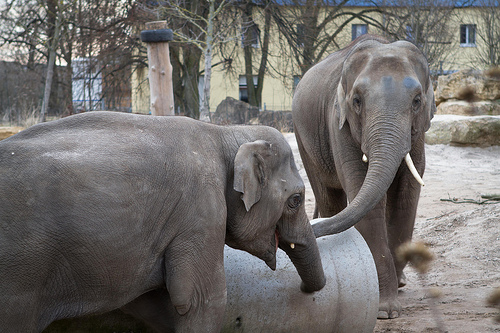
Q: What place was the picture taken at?
A: It was taken at the pen.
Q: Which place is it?
A: It is a pen.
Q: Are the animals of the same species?
A: Yes, all the animals are elephants.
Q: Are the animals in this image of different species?
A: No, all the animals are elephants.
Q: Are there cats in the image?
A: No, there are no cats.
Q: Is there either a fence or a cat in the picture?
A: No, there are no cats or fences.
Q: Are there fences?
A: No, there are no fences.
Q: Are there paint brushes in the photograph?
A: No, there are no paint brushes.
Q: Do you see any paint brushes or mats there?
A: No, there are no paint brushes or mats.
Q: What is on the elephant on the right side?
A: The trunk is on the elephant.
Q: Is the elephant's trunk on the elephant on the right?
A: Yes, the trunk is on the elephant.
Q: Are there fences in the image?
A: No, there are no fences.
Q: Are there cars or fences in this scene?
A: No, there are no fences or cars.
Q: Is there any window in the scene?
A: Yes, there is a window.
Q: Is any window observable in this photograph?
A: Yes, there is a window.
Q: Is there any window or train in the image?
A: Yes, there is a window.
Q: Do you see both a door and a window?
A: No, there is a window but no doors.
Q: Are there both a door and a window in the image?
A: No, there is a window but no doors.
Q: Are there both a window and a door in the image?
A: No, there is a window but no doors.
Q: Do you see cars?
A: No, there are no cars.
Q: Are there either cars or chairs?
A: No, there are no cars or chairs.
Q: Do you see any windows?
A: Yes, there is a window.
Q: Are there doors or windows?
A: Yes, there is a window.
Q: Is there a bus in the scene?
A: No, there are no buses.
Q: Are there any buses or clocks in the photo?
A: No, there are no buses or clocks.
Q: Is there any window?
A: Yes, there is a window.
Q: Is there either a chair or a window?
A: Yes, there is a window.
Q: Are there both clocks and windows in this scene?
A: No, there is a window but no clocks.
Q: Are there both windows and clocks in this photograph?
A: No, there is a window but no clocks.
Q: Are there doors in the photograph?
A: No, there are no doors.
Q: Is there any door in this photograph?
A: No, there are no doors.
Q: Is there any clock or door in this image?
A: No, there are no doors or clocks.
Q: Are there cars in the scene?
A: No, there are no cars.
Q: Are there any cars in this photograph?
A: No, there are no cars.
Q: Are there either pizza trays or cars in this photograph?
A: No, there are no cars or pizza trays.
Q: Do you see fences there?
A: No, there are no fences.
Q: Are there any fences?
A: No, there are no fences.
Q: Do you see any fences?
A: No, there are no fences.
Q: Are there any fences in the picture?
A: No, there are no fences.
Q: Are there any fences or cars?
A: No, there are no fences or cars.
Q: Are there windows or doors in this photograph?
A: Yes, there is a window.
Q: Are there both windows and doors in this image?
A: No, there is a window but no doors.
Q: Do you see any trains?
A: No, there are no trains.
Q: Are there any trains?
A: No, there are no trains.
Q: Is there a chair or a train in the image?
A: No, there are no trains or chairs.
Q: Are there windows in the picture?
A: Yes, there is a window.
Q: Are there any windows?
A: Yes, there is a window.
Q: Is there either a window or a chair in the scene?
A: Yes, there is a window.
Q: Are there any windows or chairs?
A: Yes, there is a window.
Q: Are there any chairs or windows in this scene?
A: Yes, there is a window.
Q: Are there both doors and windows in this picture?
A: No, there is a window but no doors.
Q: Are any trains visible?
A: No, there are no trains.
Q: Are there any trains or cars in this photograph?
A: No, there are no trains or cars.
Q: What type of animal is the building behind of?
A: The building is behind the elephant.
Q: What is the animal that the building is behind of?
A: The animal is an elephant.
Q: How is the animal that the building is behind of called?
A: The animal is an elephant.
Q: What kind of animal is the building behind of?
A: The building is behind the elephant.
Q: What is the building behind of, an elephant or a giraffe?
A: The building is behind an elephant.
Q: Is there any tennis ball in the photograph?
A: No, there are no tennis balls.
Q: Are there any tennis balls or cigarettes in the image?
A: No, there are no tennis balls or cigarettes.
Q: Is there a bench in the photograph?
A: No, there are no benches.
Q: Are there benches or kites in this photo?
A: No, there are no benches or kites.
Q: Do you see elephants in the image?
A: Yes, there is an elephant.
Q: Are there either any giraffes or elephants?
A: Yes, there is an elephant.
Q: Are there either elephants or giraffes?
A: Yes, there is an elephant.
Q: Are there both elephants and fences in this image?
A: No, there is an elephant but no fences.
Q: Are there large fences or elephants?
A: Yes, there is a large elephant.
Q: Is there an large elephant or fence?
A: Yes, there is a large elephant.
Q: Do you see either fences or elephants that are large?
A: Yes, the elephant is large.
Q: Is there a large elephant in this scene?
A: Yes, there is a large elephant.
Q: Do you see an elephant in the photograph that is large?
A: Yes, there is an elephant that is large.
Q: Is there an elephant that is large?
A: Yes, there is an elephant that is large.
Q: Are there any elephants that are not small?
A: Yes, there is a large elephant.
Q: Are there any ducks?
A: No, there are no ducks.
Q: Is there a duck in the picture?
A: No, there are no ducks.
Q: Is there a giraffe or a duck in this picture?
A: No, there are no ducks or giraffes.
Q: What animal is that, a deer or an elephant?
A: That is an elephant.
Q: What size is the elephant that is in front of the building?
A: The elephant is large.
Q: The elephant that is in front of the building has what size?
A: The elephant is large.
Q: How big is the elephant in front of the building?
A: The elephant is large.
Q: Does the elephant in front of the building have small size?
A: No, the elephant is large.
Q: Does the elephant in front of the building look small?
A: No, the elephant is large.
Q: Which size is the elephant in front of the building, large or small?
A: The elephant is large.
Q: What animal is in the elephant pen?
A: The elephant is in the pen.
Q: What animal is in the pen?
A: The elephant is in the pen.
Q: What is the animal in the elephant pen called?
A: The animal is an elephant.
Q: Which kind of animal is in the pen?
A: The animal is an elephant.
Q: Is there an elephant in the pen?
A: Yes, there is an elephant in the pen.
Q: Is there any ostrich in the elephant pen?
A: No, there is an elephant in the pen.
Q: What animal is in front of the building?
A: The elephant is in front of the building.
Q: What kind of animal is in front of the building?
A: The animal is an elephant.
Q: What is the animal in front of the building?
A: The animal is an elephant.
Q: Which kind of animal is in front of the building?
A: The animal is an elephant.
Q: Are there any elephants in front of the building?
A: Yes, there is an elephant in front of the building.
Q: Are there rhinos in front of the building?
A: No, there is an elephant in front of the building.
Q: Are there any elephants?
A: Yes, there is an elephant.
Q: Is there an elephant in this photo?
A: Yes, there is an elephant.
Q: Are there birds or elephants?
A: Yes, there is an elephant.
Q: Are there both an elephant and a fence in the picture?
A: No, there is an elephant but no fences.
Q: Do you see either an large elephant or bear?
A: Yes, there is a large elephant.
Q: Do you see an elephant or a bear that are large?
A: Yes, the elephant is large.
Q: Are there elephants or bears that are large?
A: Yes, the elephant is large.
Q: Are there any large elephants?
A: Yes, there is a large elephant.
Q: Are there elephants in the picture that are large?
A: Yes, there is an elephant that is large.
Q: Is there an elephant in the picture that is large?
A: Yes, there is an elephant that is large.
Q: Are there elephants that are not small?
A: Yes, there is a large elephant.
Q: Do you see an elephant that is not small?
A: Yes, there is a large elephant.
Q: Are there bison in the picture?
A: No, there are no bison.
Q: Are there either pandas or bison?
A: No, there are no bison or pandas.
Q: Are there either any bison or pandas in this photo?
A: No, there are no bison or pandas.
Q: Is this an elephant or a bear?
A: This is an elephant.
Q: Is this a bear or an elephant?
A: This is an elephant.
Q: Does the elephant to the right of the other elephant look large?
A: Yes, the elephant is large.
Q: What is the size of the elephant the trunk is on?
A: The elephant is large.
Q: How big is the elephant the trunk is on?
A: The elephant is large.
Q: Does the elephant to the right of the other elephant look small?
A: No, the elephant is large.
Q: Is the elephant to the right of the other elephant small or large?
A: The elephant is large.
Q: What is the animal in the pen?
A: The animal is an elephant.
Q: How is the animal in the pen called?
A: The animal is an elephant.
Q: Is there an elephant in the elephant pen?
A: Yes, there is an elephant in the pen.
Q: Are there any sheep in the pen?
A: No, there is an elephant in the pen.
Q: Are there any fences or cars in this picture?
A: No, there are no fences or cars.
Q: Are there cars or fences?
A: No, there are no fences or cars.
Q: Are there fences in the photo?
A: No, there are no fences.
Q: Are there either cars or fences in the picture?
A: No, there are no fences or cars.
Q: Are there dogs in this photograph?
A: No, there are no dogs.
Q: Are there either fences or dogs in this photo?
A: No, there are no dogs or fences.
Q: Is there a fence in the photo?
A: No, there are no fences.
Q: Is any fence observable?
A: No, there are no fences.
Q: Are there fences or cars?
A: No, there are no fences or cars.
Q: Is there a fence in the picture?
A: No, there are no fences.